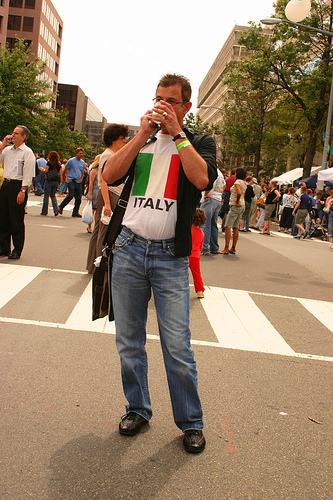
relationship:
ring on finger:
[161, 110, 169, 118] [151, 106, 169, 118]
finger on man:
[151, 106, 169, 118] [101, 71, 210, 453]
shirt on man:
[120, 128, 186, 243] [101, 71, 210, 453]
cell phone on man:
[7, 136, 13, 141] [2, 120, 37, 265]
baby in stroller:
[307, 214, 323, 232] [309, 212, 325, 238]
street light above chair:
[260, 15, 330, 167] [219, 175, 331, 259]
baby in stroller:
[315, 217, 325, 235] [309, 214, 329, 240]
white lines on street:
[0, 262, 332, 363] [1, 191, 332, 498]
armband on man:
[174, 137, 192, 154] [101, 71, 210, 453]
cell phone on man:
[8, 134, 12, 141] [0, 124, 35, 259]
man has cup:
[101, 71, 210, 453] [151, 98, 165, 125]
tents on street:
[270, 162, 331, 196] [244, 233, 330, 275]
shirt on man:
[118, 128, 186, 250] [101, 70, 220, 457]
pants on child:
[186, 252, 211, 294] [186, 210, 215, 292]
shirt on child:
[196, 228, 210, 247] [186, 200, 212, 307]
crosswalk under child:
[208, 286, 331, 364] [190, 207, 213, 302]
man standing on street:
[101, 70, 220, 457] [1, 191, 332, 498]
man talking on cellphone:
[0, 123, 36, 261] [4, 132, 14, 143]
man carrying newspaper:
[0, 124, 35, 259] [17, 160, 25, 175]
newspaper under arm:
[17, 160, 25, 175] [16, 151, 35, 205]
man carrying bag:
[101, 70, 220, 457] [90, 144, 141, 320]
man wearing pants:
[0, 124, 35, 259] [0, 176, 28, 260]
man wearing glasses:
[101, 71, 210, 453] [149, 95, 179, 105]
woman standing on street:
[217, 166, 246, 255] [189, 226, 331, 487]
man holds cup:
[101, 71, 210, 453] [152, 100, 165, 125]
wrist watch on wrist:
[171, 131, 186, 140] [169, 127, 189, 137]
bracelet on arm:
[175, 139, 191, 150] [174, 134, 216, 189]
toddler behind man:
[104, 124, 217, 260] [107, 68, 219, 454]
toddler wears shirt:
[176, 192, 245, 325] [188, 226, 204, 259]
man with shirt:
[57, 148, 86, 219] [65, 158, 86, 184]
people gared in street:
[212, 149, 326, 234] [212, 236, 326, 460]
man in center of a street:
[101, 70, 220, 457] [214, 268, 321, 490]